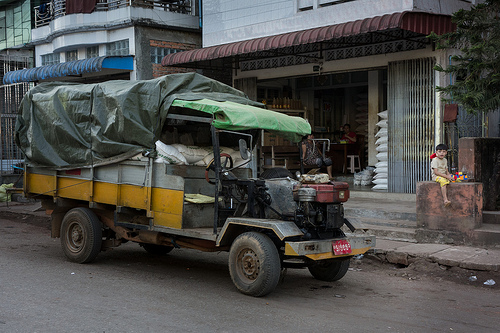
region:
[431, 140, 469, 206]
a little girl playing with a toy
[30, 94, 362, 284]
an old truck is packed on the road side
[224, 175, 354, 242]
the bonnet isnt covered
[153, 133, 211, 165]
the truck is loaded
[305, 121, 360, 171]
women sitted inside the shop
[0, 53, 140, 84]
a blue covering ouside the shop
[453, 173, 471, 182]
the toy is coloured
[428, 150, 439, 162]
the girl has a red hairband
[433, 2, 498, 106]
a green tree growing outsiide the shop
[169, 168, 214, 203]
the truck has no seat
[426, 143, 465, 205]
A child sits on a wall.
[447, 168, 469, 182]
The child holds a toy.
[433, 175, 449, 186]
The child wears yellow pants.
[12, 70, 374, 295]
A truck is on the street.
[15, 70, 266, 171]
A canopy drapes over the truck.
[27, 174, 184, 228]
The truck is orange.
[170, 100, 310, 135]
The truck's roof is covered by a green canopy.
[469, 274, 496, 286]
Litter is on the ground.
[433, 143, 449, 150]
The boy has dark hair.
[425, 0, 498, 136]
A tree is in front of the building.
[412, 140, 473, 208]
A boy sitting on the wall.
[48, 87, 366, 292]
A truck parked in front of the building.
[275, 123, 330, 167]
A person is sitting in the building.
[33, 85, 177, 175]
A tent over the back part of the truck.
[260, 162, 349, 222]
The engine of the truck.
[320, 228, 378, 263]
A red license tag in front of truck.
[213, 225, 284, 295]
The tire is dirty and muddy.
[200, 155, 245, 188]
The steering wheel of the truck.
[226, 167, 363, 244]
The truck is missing the hood.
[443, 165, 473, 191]
The boy is playing with a toy.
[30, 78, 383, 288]
Goods carrying truck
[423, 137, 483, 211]
A children sitting in the wall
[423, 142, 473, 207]
A children playing with toys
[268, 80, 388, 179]
A shop with bags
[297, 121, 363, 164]
Two womans sitting inside the shop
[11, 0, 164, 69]
Lot of buildings near the shop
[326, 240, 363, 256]
Number plate of the truck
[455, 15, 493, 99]
Tree near the shop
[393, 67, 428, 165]
A metal type shutter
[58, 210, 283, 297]
Wheels of the truck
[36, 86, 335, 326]
this is a lorry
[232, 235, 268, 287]
this is a wheel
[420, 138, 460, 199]
this is a girl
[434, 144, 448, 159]
the girl is light skinned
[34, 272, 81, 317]
this is a road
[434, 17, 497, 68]
this is a tree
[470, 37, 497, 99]
the leaves are green in color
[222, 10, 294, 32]
this is a wall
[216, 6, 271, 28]
the wall is white in color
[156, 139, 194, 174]
this is a sack